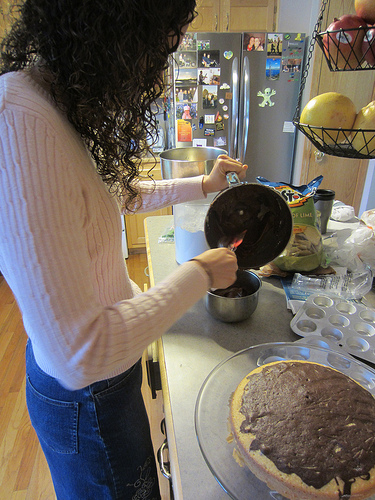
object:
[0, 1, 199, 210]
hair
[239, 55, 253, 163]
handle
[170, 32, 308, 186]
fridge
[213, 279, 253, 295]
icing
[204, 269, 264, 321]
bowl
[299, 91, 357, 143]
grapefruit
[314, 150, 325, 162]
knob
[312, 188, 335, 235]
cup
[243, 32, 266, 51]
picture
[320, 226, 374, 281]
plastic bag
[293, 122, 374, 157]
basket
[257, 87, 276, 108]
decoration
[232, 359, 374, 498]
cake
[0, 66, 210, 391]
sweater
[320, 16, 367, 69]
apple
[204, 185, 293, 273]
frosting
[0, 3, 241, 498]
woman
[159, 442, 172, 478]
pulls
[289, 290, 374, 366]
pan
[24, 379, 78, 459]
pocket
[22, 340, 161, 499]
jeans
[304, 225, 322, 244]
chips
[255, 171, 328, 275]
bag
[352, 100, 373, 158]
grapefruit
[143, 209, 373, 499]
top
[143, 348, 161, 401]
handle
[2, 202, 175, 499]
floor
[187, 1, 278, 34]
cabinet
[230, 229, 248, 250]
spatula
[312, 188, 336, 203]
lid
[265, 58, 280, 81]
picture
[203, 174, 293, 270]
bowl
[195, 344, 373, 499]
dish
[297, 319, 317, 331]
slots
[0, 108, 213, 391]
sleeves